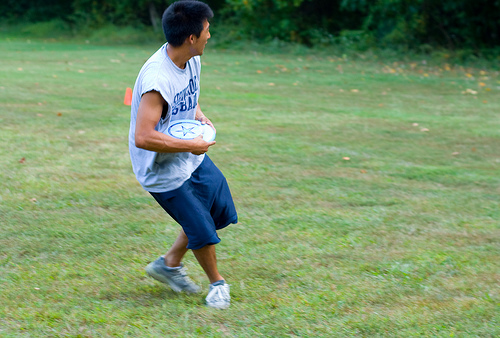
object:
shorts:
[141, 151, 241, 257]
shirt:
[120, 42, 215, 198]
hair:
[154, 0, 220, 49]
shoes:
[135, 254, 207, 301]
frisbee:
[159, 115, 218, 153]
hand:
[189, 132, 216, 158]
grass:
[0, 41, 500, 338]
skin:
[136, 115, 163, 148]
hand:
[197, 114, 217, 132]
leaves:
[462, 79, 484, 100]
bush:
[351, 0, 435, 57]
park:
[1, 1, 497, 337]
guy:
[113, 1, 251, 315]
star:
[174, 123, 198, 137]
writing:
[166, 74, 201, 116]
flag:
[118, 85, 137, 108]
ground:
[0, 46, 499, 338]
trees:
[220, 0, 307, 60]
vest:
[119, 39, 208, 197]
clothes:
[125, 43, 241, 257]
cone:
[121, 84, 135, 107]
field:
[0, 35, 496, 336]